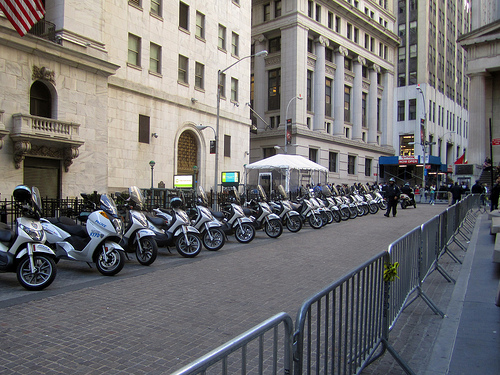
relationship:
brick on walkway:
[175, 245, 301, 306] [3, 197, 458, 373]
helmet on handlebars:
[12, 186, 32, 203] [11, 189, 43, 217]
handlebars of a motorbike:
[11, 189, 43, 217] [0, 187, 73, 287]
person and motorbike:
[378, 173, 406, 220] [320, 186, 344, 226]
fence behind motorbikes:
[381, 195, 465, 342] [8, 180, 390, 281]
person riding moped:
[398, 180, 419, 210] [397, 192, 417, 211]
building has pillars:
[252, 7, 490, 192] [304, 59, 387, 133]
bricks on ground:
[243, 216, 388, 292] [0, 199, 498, 373]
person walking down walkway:
[378, 173, 406, 220] [3, 197, 458, 373]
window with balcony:
[223, 73, 248, 106] [10, 112, 83, 171]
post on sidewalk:
[212, 47, 243, 200] [1, 196, 458, 373]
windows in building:
[281, 73, 381, 153] [252, 2, 393, 179]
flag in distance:
[453, 148, 470, 165] [382, 8, 498, 200]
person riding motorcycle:
[403, 184, 418, 204] [398, 182, 415, 203]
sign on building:
[396, 152, 423, 171] [251, 0, 451, 204]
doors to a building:
[177, 130, 199, 187] [104, 3, 251, 185]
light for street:
[415, 77, 426, 105] [124, 243, 344, 375]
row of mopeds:
[27, 196, 314, 364] [16, 141, 401, 291]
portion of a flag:
[394, 130, 489, 222] [3, 0, 55, 41]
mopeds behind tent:
[236, 148, 330, 197] [243, 151, 327, 198]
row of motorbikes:
[4, 183, 390, 293] [6, 181, 158, 285]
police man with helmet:
[378, 174, 403, 219] [386, 174, 394, 184]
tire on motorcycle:
[88, 237, 130, 277] [36, 191, 132, 275]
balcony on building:
[9, 105, 85, 170] [60, 17, 488, 244]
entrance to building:
[162, 117, 217, 208] [3, 3, 260, 238]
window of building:
[27, 76, 63, 117] [5, 2, 258, 212]